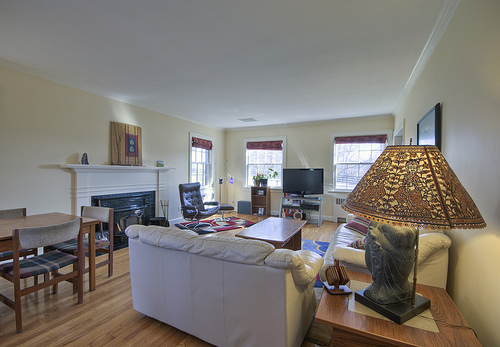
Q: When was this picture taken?
A: During the day.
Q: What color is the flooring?
A: Brown.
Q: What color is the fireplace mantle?
A: White.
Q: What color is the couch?
A: Beige.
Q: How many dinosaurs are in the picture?
A: Zero.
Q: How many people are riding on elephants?
A: Zero.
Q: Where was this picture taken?
A: In a living room.